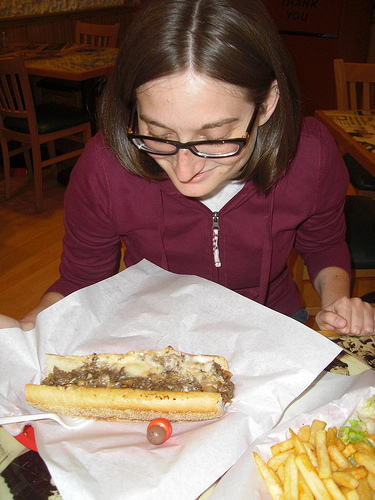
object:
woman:
[0, 5, 373, 337]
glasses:
[121, 99, 261, 160]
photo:
[0, 2, 373, 498]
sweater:
[38, 115, 353, 316]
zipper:
[210, 209, 222, 269]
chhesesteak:
[24, 345, 236, 424]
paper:
[0, 259, 342, 499]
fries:
[250, 450, 282, 499]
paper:
[201, 370, 374, 499]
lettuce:
[339, 420, 368, 452]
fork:
[2, 411, 99, 433]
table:
[3, 38, 118, 85]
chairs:
[0, 20, 92, 214]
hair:
[99, 1, 304, 196]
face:
[135, 72, 254, 197]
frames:
[127, 108, 259, 159]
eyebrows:
[199, 114, 239, 134]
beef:
[45, 361, 236, 403]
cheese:
[120, 345, 150, 376]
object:
[143, 417, 170, 445]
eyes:
[202, 128, 233, 143]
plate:
[4, 334, 245, 464]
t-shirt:
[195, 169, 246, 212]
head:
[98, 3, 301, 198]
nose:
[166, 136, 207, 183]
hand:
[314, 294, 372, 337]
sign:
[281, 0, 319, 25]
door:
[269, 1, 368, 119]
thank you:
[282, 1, 338, 25]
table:
[5, 327, 373, 500]